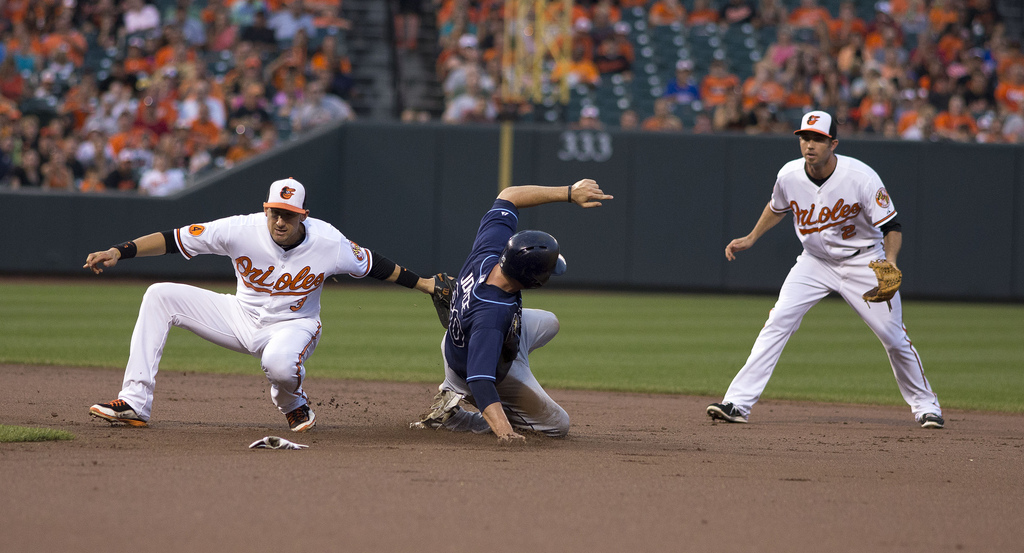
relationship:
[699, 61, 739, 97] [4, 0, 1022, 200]
spectator in stands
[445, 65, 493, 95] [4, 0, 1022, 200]
spectator in stands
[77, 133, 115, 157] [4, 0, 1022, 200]
spectator in stands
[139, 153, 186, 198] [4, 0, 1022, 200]
person in stands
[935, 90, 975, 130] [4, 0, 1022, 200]
spectator in stands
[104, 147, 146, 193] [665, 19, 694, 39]
person sitting in seat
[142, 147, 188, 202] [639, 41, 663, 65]
person sitting in seat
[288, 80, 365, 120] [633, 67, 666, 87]
person sitting in seat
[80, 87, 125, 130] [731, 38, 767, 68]
person sitting in seat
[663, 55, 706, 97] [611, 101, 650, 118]
person sitting in seat